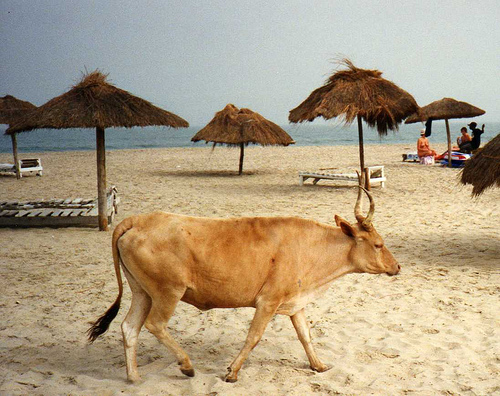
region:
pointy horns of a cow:
[352, 167, 377, 227]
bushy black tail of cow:
[86, 302, 122, 349]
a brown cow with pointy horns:
[82, 167, 406, 387]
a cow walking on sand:
[33, 206, 432, 394]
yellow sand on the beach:
[2, 140, 496, 394]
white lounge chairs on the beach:
[0, 189, 121, 226]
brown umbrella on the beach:
[188, 98, 296, 183]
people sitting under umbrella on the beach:
[397, 90, 494, 172]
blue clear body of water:
[2, 106, 492, 146]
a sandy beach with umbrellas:
[2, 2, 496, 394]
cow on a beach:
[24, 118, 381, 353]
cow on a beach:
[86, 96, 361, 368]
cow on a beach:
[210, 117, 482, 357]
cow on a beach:
[211, 103, 410, 333]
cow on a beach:
[246, 89, 460, 386]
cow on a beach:
[167, 96, 383, 371]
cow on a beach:
[97, 138, 381, 352]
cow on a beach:
[72, 189, 439, 323]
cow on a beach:
[223, 68, 472, 344]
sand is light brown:
[360, 301, 447, 391]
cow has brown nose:
[390, 240, 404, 290]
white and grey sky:
[137, 14, 267, 116]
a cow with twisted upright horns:
[98, 163, 409, 378]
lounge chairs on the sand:
[3, 186, 121, 221]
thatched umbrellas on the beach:
[194, 83, 296, 150]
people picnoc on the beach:
[418, 117, 487, 160]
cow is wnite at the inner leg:
[123, 267, 142, 386]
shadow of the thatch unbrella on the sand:
[402, 224, 499, 274]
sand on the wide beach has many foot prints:
[9, 144, 498, 395]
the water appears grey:
[9, 124, 497, 151]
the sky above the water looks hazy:
[8, 0, 495, 117]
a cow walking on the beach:
[37, 68, 428, 379]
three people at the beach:
[402, 99, 489, 182]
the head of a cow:
[333, 174, 415, 286]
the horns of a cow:
[350, 165, 375, 224]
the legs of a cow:
[98, 296, 349, 392]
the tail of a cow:
[86, 220, 127, 339]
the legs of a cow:
[121, 296, 342, 393]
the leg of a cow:
[287, 300, 341, 382]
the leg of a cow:
[222, 306, 281, 388]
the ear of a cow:
[332, 212, 356, 242]